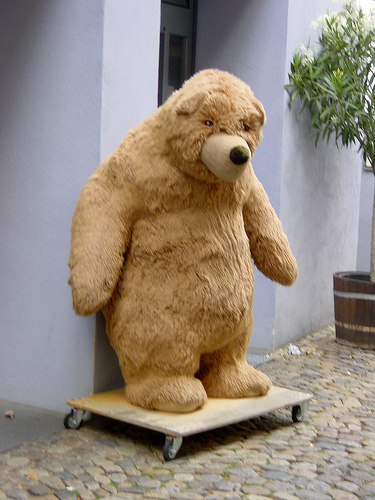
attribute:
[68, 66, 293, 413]
teddy bear — brown, large, stuffed, upset, giant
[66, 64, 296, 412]
bear — standing, stuffed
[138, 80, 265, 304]
brown bear — large, stuffed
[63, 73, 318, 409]
bear — large, teddy, brown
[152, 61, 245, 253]
bear — standing, teddy